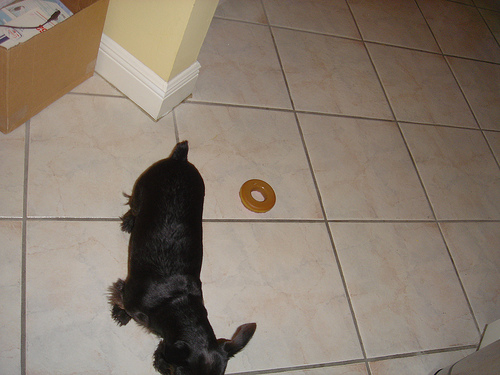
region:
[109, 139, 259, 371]
black dog with a short tail on a tiled floor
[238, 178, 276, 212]
dog chew toy ring on a white tiled floor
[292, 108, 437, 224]
white tile with gray grout on a floor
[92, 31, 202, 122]
white wooden baseboard on a tan column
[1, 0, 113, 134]
brown cardboard box sitting on tiled floor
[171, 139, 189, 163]
short tail of a black dog on the tiled floor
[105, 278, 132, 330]
right front leg and paw of a black dog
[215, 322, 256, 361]
left ear of a black dog's head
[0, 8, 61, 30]
black wire in a brown cardboard box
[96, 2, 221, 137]
tan wall on a column on a tiled floor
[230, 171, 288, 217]
Brown donut on the floor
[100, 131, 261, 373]
Small black dog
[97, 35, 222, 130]
White trim on wall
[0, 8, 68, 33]
Small black cable in box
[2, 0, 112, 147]
Brown box on the floor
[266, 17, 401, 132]
White tile floor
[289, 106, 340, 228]
Black grout in between white tiles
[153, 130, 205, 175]
Short tail on dog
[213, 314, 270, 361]
Small dog ear sticking out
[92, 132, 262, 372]
Dog walking away from camera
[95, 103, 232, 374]
the dog is black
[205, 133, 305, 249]
a brown donut on the floor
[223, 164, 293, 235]
a brown donut on the floor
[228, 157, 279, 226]
brown ring on the floor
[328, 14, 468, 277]
dirty white tiled floor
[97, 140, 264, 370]
small black dog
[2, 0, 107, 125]
brown box of stuff on the floor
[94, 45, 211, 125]
white baseboard at the bottom of the wall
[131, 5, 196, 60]
beige colored wall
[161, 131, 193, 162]
dog's tail that's been docked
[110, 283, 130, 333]
fluffy dog paw on the floor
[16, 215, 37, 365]
grey grout between the tiles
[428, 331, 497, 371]
can on the floor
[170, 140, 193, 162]
Dog has black tail.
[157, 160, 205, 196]
Dog has black rear end.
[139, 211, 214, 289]
Dog has black back.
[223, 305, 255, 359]
Dog has black ear.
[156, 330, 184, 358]
Dog has black ear.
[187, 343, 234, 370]
Dog has black head.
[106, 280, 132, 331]
Dog has black paw.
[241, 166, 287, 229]
Brown donut on floor.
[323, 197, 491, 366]
Large white tiles on floor.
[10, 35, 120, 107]
Brown box on kitchen floor.